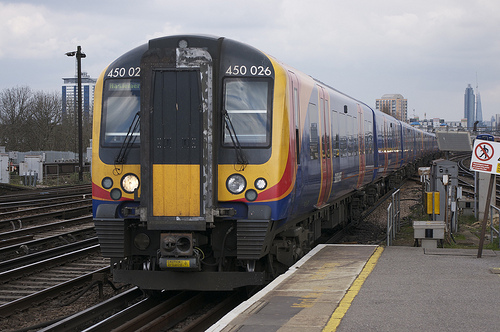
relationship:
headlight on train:
[227, 174, 247, 193] [90, 33, 437, 296]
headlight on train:
[121, 172, 138, 192] [90, 33, 437, 296]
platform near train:
[197, 241, 499, 331] [90, 33, 437, 296]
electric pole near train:
[64, 45, 86, 179] [90, 33, 437, 296]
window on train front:
[101, 77, 139, 148] [91, 36, 288, 292]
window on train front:
[222, 75, 271, 148] [91, 36, 288, 292]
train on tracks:
[90, 33, 437, 296] [0, 152, 499, 331]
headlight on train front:
[227, 174, 247, 193] [91, 36, 288, 292]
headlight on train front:
[121, 172, 138, 192] [91, 36, 288, 292]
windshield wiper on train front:
[221, 110, 247, 165] [91, 36, 288, 292]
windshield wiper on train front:
[114, 111, 141, 165] [91, 36, 288, 292]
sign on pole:
[470, 137, 499, 176] [477, 174, 497, 259]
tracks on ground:
[0, 152, 499, 331] [2, 152, 496, 331]